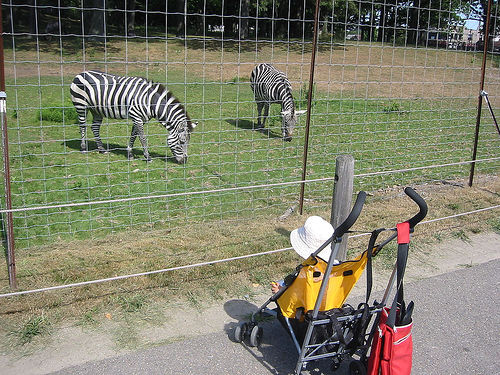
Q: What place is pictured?
A: It is a road.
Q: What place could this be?
A: It is a road.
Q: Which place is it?
A: It is a road.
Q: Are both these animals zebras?
A: Yes, all the animals are zebras.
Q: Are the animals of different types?
A: No, all the animals are zebras.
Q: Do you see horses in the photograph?
A: No, there are no horses.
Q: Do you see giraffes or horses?
A: No, there are no horses or giraffes.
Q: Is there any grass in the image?
A: Yes, there is grass.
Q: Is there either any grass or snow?
A: Yes, there is grass.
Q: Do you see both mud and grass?
A: No, there is grass but no mud.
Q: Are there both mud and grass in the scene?
A: No, there is grass but no mud.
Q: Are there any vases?
A: No, there are no vases.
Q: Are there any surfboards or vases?
A: No, there are no vases or surfboards.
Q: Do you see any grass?
A: Yes, there is grass.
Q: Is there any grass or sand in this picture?
A: Yes, there is grass.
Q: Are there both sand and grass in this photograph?
A: No, there is grass but no sand.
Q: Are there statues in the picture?
A: No, there are no statues.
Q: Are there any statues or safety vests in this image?
A: No, there are no statues or safety vests.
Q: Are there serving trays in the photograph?
A: No, there are no serving trays.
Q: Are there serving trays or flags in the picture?
A: No, there are no serving trays or flags.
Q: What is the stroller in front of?
A: The stroller is in front of the fence.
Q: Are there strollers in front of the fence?
A: Yes, there is a stroller in front of the fence.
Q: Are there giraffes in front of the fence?
A: No, there is a stroller in front of the fence.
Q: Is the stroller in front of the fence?
A: Yes, the stroller is in front of the fence.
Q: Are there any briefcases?
A: No, there are no briefcases.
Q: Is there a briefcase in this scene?
A: No, there are no briefcases.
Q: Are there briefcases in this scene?
A: No, there are no briefcases.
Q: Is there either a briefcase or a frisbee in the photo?
A: No, there are no briefcases or frisbees.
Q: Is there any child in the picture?
A: Yes, there is a child.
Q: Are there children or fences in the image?
A: Yes, there is a child.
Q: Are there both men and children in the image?
A: No, there is a child but no men.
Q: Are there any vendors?
A: No, there are no vendors.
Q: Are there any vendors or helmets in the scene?
A: No, there are no vendors or helmets.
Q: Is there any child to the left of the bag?
A: Yes, there is a child to the left of the bag.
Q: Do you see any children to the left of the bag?
A: Yes, there is a child to the left of the bag.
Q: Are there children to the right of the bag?
A: No, the child is to the left of the bag.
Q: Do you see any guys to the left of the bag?
A: No, there is a child to the left of the bag.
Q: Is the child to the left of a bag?
A: Yes, the child is to the left of a bag.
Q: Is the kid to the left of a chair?
A: No, the kid is to the left of a bag.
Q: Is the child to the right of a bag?
A: No, the child is to the left of a bag.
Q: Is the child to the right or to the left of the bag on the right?
A: The child is to the left of the bag.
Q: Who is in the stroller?
A: The kid is in the stroller.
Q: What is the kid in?
A: The kid is in the stroller.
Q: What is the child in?
A: The kid is in the stroller.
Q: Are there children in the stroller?
A: Yes, there is a child in the stroller.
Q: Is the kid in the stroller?
A: Yes, the kid is in the stroller.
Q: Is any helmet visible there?
A: No, there are no helmets.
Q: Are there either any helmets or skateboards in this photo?
A: No, there are no helmets or skateboards.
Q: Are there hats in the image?
A: Yes, there is a hat.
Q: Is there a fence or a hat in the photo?
A: Yes, there is a hat.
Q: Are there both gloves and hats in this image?
A: No, there is a hat but no gloves.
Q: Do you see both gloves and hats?
A: No, there is a hat but no gloves.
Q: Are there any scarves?
A: No, there are no scarves.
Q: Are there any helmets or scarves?
A: No, there are no scarves or helmets.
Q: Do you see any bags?
A: Yes, there is a bag.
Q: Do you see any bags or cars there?
A: Yes, there is a bag.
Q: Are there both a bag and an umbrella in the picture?
A: No, there is a bag but no umbrellas.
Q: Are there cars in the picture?
A: No, there are no cars.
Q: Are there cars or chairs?
A: No, there are no cars or chairs.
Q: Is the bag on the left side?
A: No, the bag is on the right of the image.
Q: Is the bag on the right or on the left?
A: The bag is on the right of the image.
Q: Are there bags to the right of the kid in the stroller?
A: Yes, there is a bag to the right of the kid.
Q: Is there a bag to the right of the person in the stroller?
A: Yes, there is a bag to the right of the kid.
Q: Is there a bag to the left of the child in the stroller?
A: No, the bag is to the right of the child.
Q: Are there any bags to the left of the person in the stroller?
A: No, the bag is to the right of the child.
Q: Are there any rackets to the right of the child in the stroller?
A: No, there is a bag to the right of the child.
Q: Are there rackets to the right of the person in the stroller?
A: No, there is a bag to the right of the child.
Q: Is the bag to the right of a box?
A: No, the bag is to the right of the kid.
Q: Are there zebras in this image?
A: Yes, there is a zebra.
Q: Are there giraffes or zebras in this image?
A: Yes, there is a zebra.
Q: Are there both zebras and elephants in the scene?
A: No, there is a zebra but no elephants.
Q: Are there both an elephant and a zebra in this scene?
A: No, there is a zebra but no elephants.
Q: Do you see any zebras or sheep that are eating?
A: Yes, the zebra is eating.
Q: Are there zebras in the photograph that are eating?
A: Yes, there is a zebra that is eating.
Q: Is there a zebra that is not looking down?
A: Yes, there is a zebra that is eating.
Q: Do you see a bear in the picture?
A: No, there are no bears.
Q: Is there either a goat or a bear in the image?
A: No, there are no bears or goats.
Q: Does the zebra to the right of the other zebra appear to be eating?
A: Yes, the zebra is eating.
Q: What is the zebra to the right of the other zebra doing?
A: The zebra is eating.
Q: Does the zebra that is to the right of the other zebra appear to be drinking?
A: No, the zebra is eating.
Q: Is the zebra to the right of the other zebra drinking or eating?
A: The zebra is eating.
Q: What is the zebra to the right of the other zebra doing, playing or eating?
A: The zebra is eating.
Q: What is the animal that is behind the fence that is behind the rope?
A: The animal is a zebra.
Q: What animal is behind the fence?
A: The animal is a zebra.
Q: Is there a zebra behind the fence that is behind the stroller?
A: Yes, there is a zebra behind the fence.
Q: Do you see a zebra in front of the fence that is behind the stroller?
A: No, the zebra is behind the fence.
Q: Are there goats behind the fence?
A: No, there is a zebra behind the fence.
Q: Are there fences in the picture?
A: Yes, there is a fence.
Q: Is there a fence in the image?
A: Yes, there is a fence.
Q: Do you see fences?
A: Yes, there is a fence.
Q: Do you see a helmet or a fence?
A: Yes, there is a fence.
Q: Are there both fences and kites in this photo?
A: No, there is a fence but no kites.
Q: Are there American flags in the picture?
A: No, there are no American flags.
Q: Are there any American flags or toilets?
A: No, there are no American flags or toilets.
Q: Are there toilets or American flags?
A: No, there are no American flags or toilets.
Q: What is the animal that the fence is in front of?
A: The animal is a zebra.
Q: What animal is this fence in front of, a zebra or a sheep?
A: The fence is in front of a zebra.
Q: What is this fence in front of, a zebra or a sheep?
A: The fence is in front of a zebra.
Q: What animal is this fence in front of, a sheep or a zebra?
A: The fence is in front of a zebra.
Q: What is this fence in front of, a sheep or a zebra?
A: The fence is in front of a zebra.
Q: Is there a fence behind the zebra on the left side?
A: No, the fence is in front of the zebra.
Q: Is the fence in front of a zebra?
A: Yes, the fence is in front of a zebra.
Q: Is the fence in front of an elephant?
A: No, the fence is in front of a zebra.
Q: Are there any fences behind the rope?
A: Yes, there is a fence behind the rope.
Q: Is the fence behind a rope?
A: Yes, the fence is behind a rope.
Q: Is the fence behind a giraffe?
A: No, the fence is behind a rope.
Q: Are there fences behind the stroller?
A: Yes, there is a fence behind the stroller.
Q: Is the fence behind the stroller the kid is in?
A: Yes, the fence is behind the stroller.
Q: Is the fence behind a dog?
A: No, the fence is behind the stroller.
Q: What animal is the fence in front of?
A: The fence is in front of the zebra.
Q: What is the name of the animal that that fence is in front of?
A: The animal is a zebra.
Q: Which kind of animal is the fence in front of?
A: The fence is in front of the zebra.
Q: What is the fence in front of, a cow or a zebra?
A: The fence is in front of a zebra.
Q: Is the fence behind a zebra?
A: No, the fence is in front of a zebra.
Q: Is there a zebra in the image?
A: Yes, there is a zebra.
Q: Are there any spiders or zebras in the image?
A: Yes, there is a zebra.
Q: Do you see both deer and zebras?
A: No, there is a zebra but no deer.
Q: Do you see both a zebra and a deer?
A: No, there is a zebra but no deer.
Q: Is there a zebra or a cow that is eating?
A: Yes, the zebra is eating.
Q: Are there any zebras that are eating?
A: Yes, there is a zebra that is eating.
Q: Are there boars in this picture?
A: No, there are no boars.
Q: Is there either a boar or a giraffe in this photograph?
A: No, there are no boars or giraffes.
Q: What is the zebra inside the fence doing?
A: The zebra is eating.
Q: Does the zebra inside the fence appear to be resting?
A: No, the zebra is eating.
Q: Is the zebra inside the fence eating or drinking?
A: The zebra is eating.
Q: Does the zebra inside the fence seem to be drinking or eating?
A: The zebra is eating.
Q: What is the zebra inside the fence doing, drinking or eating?
A: The zebra is eating.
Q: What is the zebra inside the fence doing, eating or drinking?
A: The zebra is eating.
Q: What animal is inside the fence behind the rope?
A: The animal is a zebra.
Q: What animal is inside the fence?
A: The animal is a zebra.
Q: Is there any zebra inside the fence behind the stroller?
A: Yes, there is a zebra inside the fence.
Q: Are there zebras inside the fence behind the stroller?
A: Yes, there is a zebra inside the fence.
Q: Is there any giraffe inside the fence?
A: No, there is a zebra inside the fence.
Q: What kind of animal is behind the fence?
A: The animal is a zebra.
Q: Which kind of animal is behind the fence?
A: The animal is a zebra.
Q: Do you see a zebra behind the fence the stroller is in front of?
A: Yes, there is a zebra behind the fence.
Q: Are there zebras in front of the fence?
A: No, the zebra is behind the fence.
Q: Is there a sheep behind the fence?
A: No, there is a zebra behind the fence.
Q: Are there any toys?
A: No, there are no toys.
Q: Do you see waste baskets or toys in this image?
A: No, there are no toys or waste baskets.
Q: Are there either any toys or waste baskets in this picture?
A: No, there are no toys or waste baskets.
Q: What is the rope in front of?
A: The rope is in front of the fence.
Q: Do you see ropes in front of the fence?
A: Yes, there is a rope in front of the fence.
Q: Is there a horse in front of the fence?
A: No, there is a rope in front of the fence.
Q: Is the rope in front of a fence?
A: Yes, the rope is in front of a fence.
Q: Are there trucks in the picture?
A: No, there are no trucks.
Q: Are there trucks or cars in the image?
A: No, there are no trucks or cars.